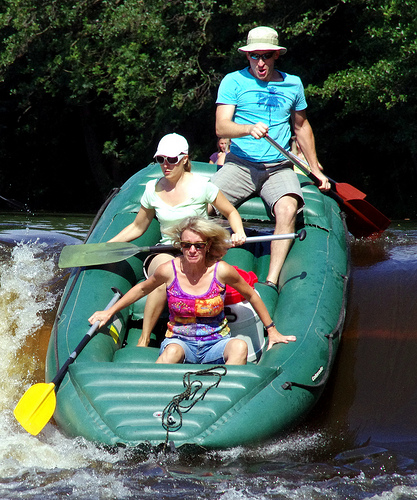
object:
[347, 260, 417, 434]
waterfall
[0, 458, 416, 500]
river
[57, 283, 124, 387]
paddle handle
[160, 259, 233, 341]
tank top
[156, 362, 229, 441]
rope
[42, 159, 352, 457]
raft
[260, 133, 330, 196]
paddle handle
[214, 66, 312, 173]
shirt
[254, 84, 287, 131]
palm tree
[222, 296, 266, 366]
canister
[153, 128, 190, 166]
baseball cap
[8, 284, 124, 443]
oar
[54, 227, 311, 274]
oar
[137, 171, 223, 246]
blouse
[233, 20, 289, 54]
brimmed hat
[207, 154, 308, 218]
shorts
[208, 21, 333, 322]
man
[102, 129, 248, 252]
woman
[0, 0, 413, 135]
trees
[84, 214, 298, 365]
woman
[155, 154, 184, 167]
sunglasses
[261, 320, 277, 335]
wrist watch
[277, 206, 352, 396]
rope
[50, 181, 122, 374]
rope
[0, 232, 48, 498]
rapids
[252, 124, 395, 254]
oars